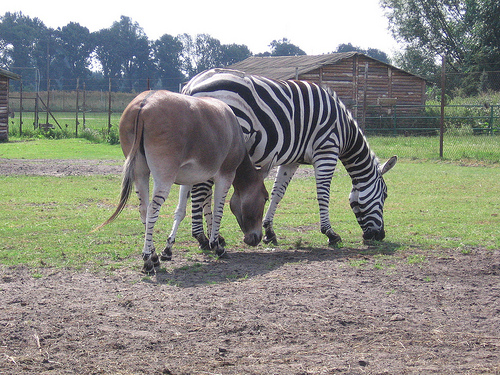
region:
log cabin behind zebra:
[222, 40, 437, 151]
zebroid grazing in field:
[86, 83, 287, 284]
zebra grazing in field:
[170, 58, 399, 250]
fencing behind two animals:
[2, 66, 134, 141]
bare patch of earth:
[4, 233, 494, 372]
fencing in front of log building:
[350, 97, 498, 136]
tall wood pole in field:
[437, 48, 445, 160]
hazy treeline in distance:
[2, 6, 231, 89]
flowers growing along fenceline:
[7, 114, 122, 138]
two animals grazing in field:
[95, 53, 407, 278]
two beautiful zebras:
[83, 60, 413, 270]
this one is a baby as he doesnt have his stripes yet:
[132, 77, 283, 269]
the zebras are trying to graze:
[10, 5, 490, 365]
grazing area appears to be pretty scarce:
[30, 147, 486, 372]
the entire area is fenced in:
[339, 95, 499, 140]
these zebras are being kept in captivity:
[25, 45, 494, 274]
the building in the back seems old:
[227, 32, 459, 144]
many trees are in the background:
[3, 6, 478, 94]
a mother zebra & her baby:
[118, 69, 418, 324]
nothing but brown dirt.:
[49, 262, 492, 365]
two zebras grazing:
[88, 43, 423, 308]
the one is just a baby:
[14, 60, 491, 295]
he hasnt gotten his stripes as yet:
[94, 51, 306, 290]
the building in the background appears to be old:
[228, 24, 468, 148]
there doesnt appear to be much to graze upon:
[27, 147, 498, 372]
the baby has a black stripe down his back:
[98, 86, 219, 236]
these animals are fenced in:
[16, 70, 131, 136]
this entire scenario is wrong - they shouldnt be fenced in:
[28, 38, 498, 366]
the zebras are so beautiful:
[166, 24, 444, 236]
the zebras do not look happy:
[5, 5, 497, 370]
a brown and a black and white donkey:
[83, 40, 448, 323]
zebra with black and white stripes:
[175, 35, 455, 295]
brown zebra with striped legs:
[95, 73, 286, 278]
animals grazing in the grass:
[82, 39, 444, 359]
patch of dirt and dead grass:
[16, 211, 479, 364]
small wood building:
[164, 28, 473, 155]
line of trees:
[8, 4, 373, 132]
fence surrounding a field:
[350, 79, 492, 143]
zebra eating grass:
[328, 167, 436, 287]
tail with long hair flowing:
[83, 93, 173, 241]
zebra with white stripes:
[187, 58, 419, 266]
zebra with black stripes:
[197, 61, 467, 284]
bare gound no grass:
[20, 276, 477, 348]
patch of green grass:
[0, 160, 491, 292]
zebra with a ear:
[289, 86, 427, 247]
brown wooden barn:
[172, 35, 453, 171]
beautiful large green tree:
[338, 3, 485, 102]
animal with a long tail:
[54, 63, 275, 310]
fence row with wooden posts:
[0, 67, 192, 158]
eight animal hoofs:
[90, 179, 413, 298]